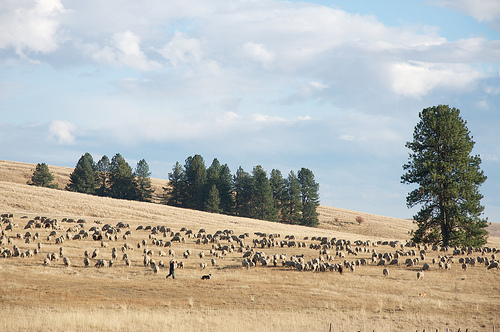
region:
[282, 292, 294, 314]
the grass is dry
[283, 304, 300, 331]
the grass is dry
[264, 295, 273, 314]
the grass is dry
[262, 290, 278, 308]
the grass is dry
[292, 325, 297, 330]
the grass is dry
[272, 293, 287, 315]
the grass is dry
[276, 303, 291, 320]
the grass is dry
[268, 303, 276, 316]
the grass is dry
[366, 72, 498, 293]
the tallest tree in the picture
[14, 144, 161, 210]
a row of trees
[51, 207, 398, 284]
a bunch of birds on the ground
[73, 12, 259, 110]
a cloudy blue sky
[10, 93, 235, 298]
trees in the background with birds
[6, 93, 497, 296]
a photo of birds and a bunch of trees in the background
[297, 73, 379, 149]
part of a blue cloudy sky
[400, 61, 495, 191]
part of a tall tree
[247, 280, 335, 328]
dead grass on the ground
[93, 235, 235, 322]
a person running with the birds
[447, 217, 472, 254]
the tree is tall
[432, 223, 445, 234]
the tree is tall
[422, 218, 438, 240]
the tree is tall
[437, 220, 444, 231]
the tree is tall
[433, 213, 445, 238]
the tree is tall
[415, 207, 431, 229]
the tree is tall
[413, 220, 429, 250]
the tree is tall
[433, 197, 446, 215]
the tree is tall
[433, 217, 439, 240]
the tree is tall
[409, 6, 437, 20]
light blue sky between clouds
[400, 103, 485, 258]
a tall pine tree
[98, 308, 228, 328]
tall yellow grass on ground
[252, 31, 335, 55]
white clouds in the sky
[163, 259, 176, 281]
a man in the field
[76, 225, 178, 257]
a group of animals in the field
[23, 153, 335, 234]
green trees in the background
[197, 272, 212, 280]
a black and white dog in the field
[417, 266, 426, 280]
a sheep in the field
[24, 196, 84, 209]
yellow glass on hill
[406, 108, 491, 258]
tall pine to right of forest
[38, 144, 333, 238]
forest of pines in background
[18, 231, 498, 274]
many animals in field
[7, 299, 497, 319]
thin, wispy grasses in field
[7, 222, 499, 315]
hill is bare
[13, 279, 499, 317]
grasses are golden brown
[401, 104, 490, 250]
tree is tall and green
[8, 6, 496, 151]
sky is slightly cloudy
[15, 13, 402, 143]
puffy clouds in sky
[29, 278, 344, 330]
dark brown ground